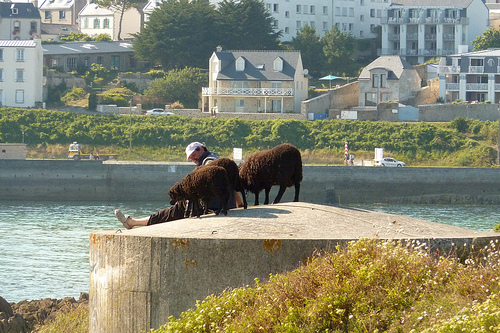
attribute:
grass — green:
[38, 245, 487, 332]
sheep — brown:
[204, 154, 244, 203]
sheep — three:
[168, 140, 310, 217]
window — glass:
[379, 92, 394, 102]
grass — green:
[149, 224, 499, 331]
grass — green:
[332, 261, 442, 318]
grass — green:
[303, 283, 425, 318]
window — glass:
[100, 16, 107, 29]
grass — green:
[188, 244, 450, 330]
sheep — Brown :
[164, 163, 230, 214]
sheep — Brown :
[240, 143, 300, 198]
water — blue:
[3, 204, 58, 259]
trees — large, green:
[212, 0, 282, 46]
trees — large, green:
[131, 0, 226, 68]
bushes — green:
[5, 108, 447, 151]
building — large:
[362, 7, 494, 105]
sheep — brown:
[169, 160, 235, 217]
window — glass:
[267, 79, 287, 94]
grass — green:
[225, 290, 498, 330]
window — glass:
[235, 59, 244, 71]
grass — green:
[148, 236, 497, 329]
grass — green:
[142, 215, 498, 332]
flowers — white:
[370, 215, 499, 295]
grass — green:
[150, 242, 499, 332]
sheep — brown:
[158, 158, 239, 213]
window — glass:
[295, 2, 302, 16]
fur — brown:
[177, 168, 237, 210]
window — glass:
[383, 72, 396, 97]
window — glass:
[237, 82, 242, 89]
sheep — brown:
[255, 127, 306, 192]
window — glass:
[360, 90, 378, 106]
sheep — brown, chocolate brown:
[165, 163, 233, 218]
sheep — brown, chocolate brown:
[234, 141, 304, 204]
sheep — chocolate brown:
[193, 156, 250, 208]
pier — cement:
[85, 196, 485, 329]